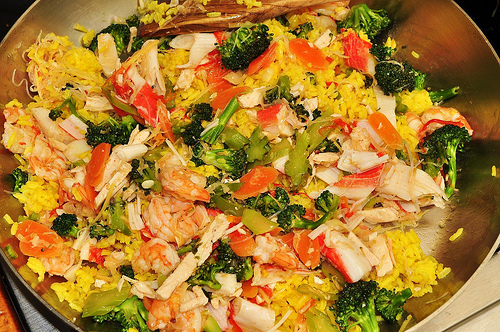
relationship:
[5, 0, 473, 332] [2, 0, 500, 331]
meal inside bowl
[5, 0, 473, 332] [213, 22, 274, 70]
meal has broccoli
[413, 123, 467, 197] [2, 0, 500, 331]
broccoli inside bowl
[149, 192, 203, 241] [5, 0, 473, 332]
shrimp inside meal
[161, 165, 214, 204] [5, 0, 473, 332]
shrimp inside meal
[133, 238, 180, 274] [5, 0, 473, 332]
shrimp inside meal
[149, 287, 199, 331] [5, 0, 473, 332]
shrimp inside meal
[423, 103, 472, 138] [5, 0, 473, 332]
shrimp inside meal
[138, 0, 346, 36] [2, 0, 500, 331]
spoon inside bowl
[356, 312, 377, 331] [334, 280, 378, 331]
stem of broccoli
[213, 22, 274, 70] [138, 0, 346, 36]
broccoli next to spoon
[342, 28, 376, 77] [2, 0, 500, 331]
crab in bowl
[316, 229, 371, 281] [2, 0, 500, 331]
crab in bowl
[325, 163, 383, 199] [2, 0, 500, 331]
crab in bowl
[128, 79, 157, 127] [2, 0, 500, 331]
crab in bowl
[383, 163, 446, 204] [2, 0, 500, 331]
crab in bowl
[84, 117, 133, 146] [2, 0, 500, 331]
broccoli in bowl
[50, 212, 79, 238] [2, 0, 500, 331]
broccoli in bowl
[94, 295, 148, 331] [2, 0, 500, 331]
broccoli in bowl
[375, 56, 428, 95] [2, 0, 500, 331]
broccoli in bowl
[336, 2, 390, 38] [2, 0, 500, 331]
broccoli in bowl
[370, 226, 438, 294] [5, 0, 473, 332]
rice part of meal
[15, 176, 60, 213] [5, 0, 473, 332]
rice part of meal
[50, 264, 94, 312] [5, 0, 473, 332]
rice part of meal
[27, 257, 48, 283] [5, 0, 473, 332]
rice part of meal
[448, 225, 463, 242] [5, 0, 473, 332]
rice part of meal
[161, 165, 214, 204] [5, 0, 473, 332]
shrimp mixed into meal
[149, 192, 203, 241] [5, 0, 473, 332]
shrimp mixed into meal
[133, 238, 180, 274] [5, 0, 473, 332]
shrimp mixed into meal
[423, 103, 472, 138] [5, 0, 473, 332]
shrimp mixed into meal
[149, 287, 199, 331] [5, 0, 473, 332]
shrimp mixed into meal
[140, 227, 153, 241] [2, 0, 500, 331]
red pepper inside bowl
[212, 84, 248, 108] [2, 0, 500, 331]
red pepper inside bowl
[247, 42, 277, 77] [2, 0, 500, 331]
red pepper inside bowl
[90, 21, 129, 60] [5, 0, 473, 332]
broccoli inside meal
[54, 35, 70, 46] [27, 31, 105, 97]
grain of rice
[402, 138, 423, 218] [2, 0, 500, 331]
noodle inside bowl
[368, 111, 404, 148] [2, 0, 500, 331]
carrot inside bowl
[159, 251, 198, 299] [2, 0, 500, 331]
chunk inside bowl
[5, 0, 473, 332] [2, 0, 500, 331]
meal in bowl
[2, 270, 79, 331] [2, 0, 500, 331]
table under bowl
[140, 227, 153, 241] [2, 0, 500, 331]
red pepper in bowl